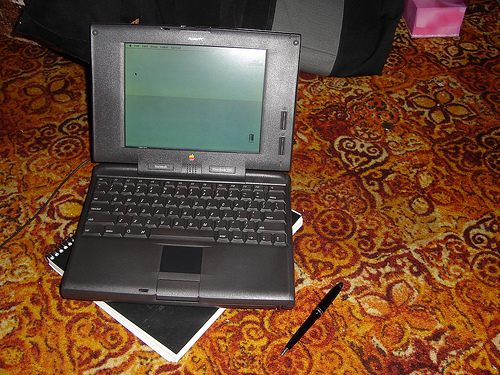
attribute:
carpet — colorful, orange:
[350, 113, 497, 291]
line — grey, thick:
[53, 19, 417, 69]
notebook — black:
[120, 307, 221, 352]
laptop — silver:
[81, 31, 298, 295]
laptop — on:
[59, 21, 301, 308]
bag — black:
[9, 0, 418, 82]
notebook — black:
[39, 202, 309, 373]